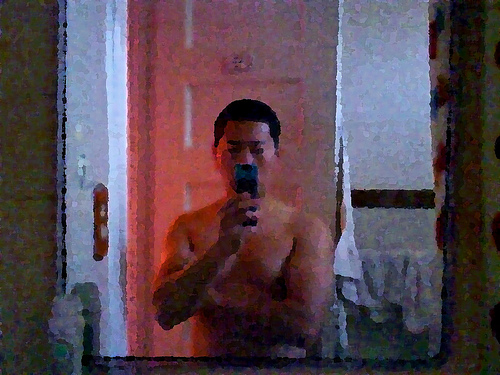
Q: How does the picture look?
A: Blurry.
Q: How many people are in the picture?
A: One.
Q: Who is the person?
A: A man.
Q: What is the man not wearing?
A: A shirt.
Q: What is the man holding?
A: Phone.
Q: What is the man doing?
A: Taking selfie.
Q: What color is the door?
A: White.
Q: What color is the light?
A: Red.